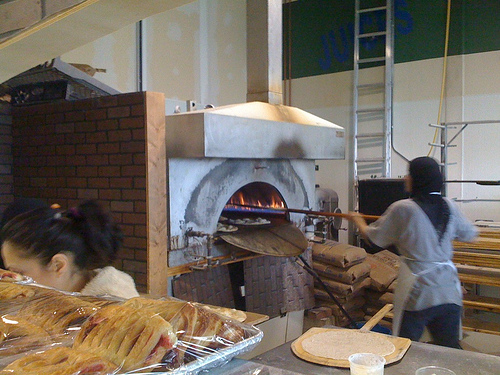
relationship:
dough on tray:
[296, 323, 398, 362] [289, 302, 415, 369]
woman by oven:
[351, 153, 478, 353] [166, 101, 350, 317]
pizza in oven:
[207, 201, 271, 233] [166, 101, 350, 317]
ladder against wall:
[351, 0, 394, 255] [251, 1, 499, 242]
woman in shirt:
[351, 153, 478, 353] [370, 199, 483, 307]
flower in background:
[311, 238, 399, 324] [251, 1, 499, 242]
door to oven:
[219, 220, 308, 260] [166, 101, 350, 317]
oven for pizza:
[166, 101, 350, 317] [207, 201, 271, 233]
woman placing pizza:
[351, 153, 478, 353] [207, 201, 271, 233]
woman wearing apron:
[351, 153, 478, 353] [392, 260, 458, 337]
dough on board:
[296, 323, 398, 362] [289, 302, 415, 369]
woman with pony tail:
[4, 199, 151, 304] [3, 198, 126, 264]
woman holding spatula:
[351, 153, 478, 353] [233, 199, 377, 227]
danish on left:
[0, 266, 260, 375] [0, 131, 5, 372]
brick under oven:
[174, 233, 319, 316] [166, 101, 350, 317]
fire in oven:
[232, 183, 285, 208] [166, 101, 350, 317]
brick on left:
[3, 91, 166, 293] [0, 131, 5, 372]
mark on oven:
[267, 105, 310, 163] [166, 101, 350, 317]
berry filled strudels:
[152, 333, 175, 355] [0, 266, 260, 375]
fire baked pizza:
[232, 183, 285, 208] [207, 201, 271, 233]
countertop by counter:
[4, 199, 151, 304] [276, 318, 497, 369]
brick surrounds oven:
[174, 233, 319, 316] [166, 101, 350, 317]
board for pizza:
[289, 302, 415, 369] [207, 201, 271, 233]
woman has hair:
[4, 199, 151, 304] [3, 198, 126, 264]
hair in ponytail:
[3, 198, 126, 264] [58, 199, 121, 263]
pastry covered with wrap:
[0, 266, 260, 375] [4, 284, 217, 372]